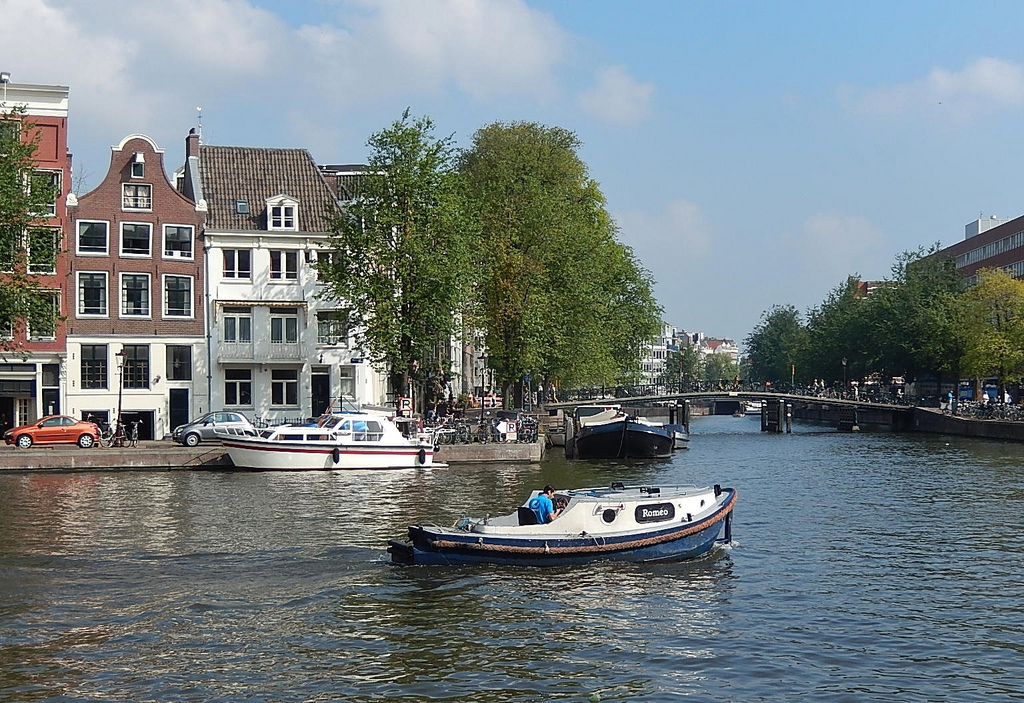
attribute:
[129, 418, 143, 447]
bicycle — red 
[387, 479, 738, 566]
window — round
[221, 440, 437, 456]
stripe — red 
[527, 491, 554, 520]
shirt — blue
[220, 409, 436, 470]
boat — parked, white 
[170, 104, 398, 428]
building — white , tall 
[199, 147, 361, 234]
roof — brown 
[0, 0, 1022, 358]
sky — blue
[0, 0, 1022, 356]
clouds — white 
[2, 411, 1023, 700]
ripples — dark 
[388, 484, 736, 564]
boat — blue, white 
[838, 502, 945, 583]
ripples — dark